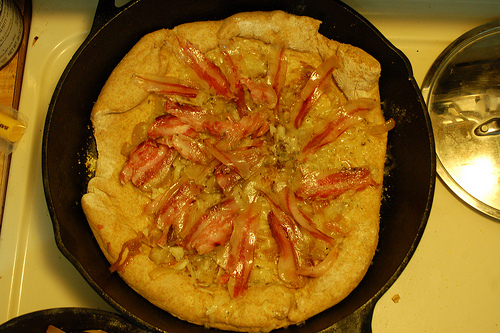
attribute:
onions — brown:
[121, 41, 396, 292]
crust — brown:
[85, 14, 390, 329]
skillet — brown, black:
[41, 2, 441, 332]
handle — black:
[324, 304, 376, 332]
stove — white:
[6, 4, 499, 325]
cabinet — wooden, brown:
[4, 4, 29, 208]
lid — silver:
[422, 19, 500, 221]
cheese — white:
[137, 50, 367, 285]